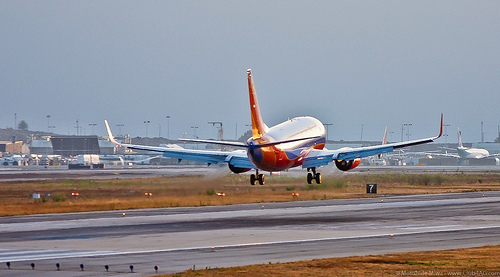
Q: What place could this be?
A: It is an airport.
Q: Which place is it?
A: It is an airport.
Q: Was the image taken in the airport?
A: Yes, it was taken in the airport.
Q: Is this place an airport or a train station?
A: It is an airport.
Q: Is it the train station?
A: No, it is the airport.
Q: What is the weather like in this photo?
A: It is clear.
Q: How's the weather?
A: It is clear.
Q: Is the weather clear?
A: Yes, it is clear.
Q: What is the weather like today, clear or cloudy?
A: It is clear.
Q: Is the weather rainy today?
A: No, it is clear.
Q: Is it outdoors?
A: Yes, it is outdoors.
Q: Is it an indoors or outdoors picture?
A: It is outdoors.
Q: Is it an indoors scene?
A: No, it is outdoors.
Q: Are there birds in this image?
A: No, there are no birds.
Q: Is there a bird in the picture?
A: No, there are no birds.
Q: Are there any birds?
A: No, there are no birds.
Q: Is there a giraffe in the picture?
A: No, there are no giraffes.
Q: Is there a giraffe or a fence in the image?
A: No, there are no giraffes or fences.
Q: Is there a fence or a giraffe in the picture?
A: No, there are no giraffes or fences.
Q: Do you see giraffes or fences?
A: No, there are no giraffes or fences.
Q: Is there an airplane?
A: Yes, there is an airplane.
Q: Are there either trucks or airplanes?
A: Yes, there is an airplane.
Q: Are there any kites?
A: No, there are no kites.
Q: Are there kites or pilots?
A: No, there are no kites or pilots.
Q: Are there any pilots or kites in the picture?
A: No, there are no kites or pilots.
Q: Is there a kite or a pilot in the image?
A: No, there are no kites or pilots.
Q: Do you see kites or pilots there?
A: No, there are no kites or pilots.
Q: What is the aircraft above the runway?
A: The aircraft is an airplane.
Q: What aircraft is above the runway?
A: The aircraft is an airplane.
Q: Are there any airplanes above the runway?
A: Yes, there is an airplane above the runway.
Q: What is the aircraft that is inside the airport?
A: The aircraft is an airplane.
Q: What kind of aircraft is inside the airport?
A: The aircraft is an airplane.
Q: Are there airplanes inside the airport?
A: Yes, there is an airplane inside the airport.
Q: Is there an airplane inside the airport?
A: Yes, there is an airplane inside the airport.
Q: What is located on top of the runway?
A: The airplane is on top of the runway.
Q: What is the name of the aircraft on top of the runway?
A: The aircraft is an airplane.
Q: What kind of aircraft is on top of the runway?
A: The aircraft is an airplane.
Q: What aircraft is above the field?
A: The aircraft is an airplane.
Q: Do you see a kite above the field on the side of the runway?
A: No, there is an airplane above the field.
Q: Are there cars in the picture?
A: No, there are no cars.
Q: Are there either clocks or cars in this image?
A: No, there are no cars or clocks.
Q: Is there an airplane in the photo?
A: Yes, there is an airplane.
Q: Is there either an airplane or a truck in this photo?
A: Yes, there is an airplane.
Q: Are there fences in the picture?
A: No, there are no fences.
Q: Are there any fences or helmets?
A: No, there are no fences or helmets.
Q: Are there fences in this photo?
A: No, there are no fences.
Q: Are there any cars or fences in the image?
A: No, there are no fences or cars.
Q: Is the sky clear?
A: Yes, the sky is clear.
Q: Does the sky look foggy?
A: No, the sky is clear.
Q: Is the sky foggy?
A: No, the sky is clear.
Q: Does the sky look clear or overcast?
A: The sky is clear.